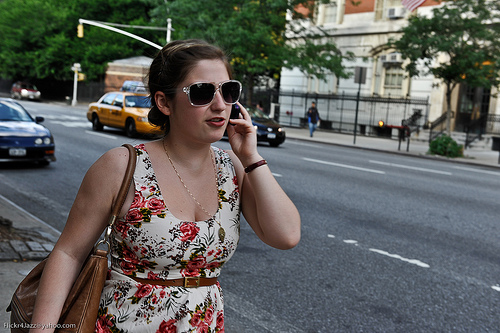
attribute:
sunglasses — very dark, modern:
[165, 78, 243, 107]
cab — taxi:
[82, 76, 162, 139]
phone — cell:
[226, 100, 241, 128]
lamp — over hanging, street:
[74, 21, 85, 40]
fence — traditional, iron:
[37, 76, 429, 141]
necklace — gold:
[158, 140, 228, 242]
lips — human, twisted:
[198, 115, 227, 127]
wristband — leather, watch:
[239, 157, 269, 173]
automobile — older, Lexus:
[0, 95, 60, 175]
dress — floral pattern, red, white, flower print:
[91, 141, 244, 331]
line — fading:
[340, 234, 430, 277]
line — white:
[338, 224, 436, 291]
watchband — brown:
[239, 158, 270, 173]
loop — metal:
[93, 235, 114, 256]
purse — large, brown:
[5, 139, 142, 328]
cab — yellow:
[84, 87, 162, 140]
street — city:
[12, 98, 499, 327]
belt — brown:
[135, 273, 224, 293]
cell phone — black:
[231, 101, 241, 121]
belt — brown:
[172, 264, 209, 298]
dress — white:
[123, 168, 255, 328]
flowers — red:
[180, 250, 206, 269]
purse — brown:
[43, 259, 119, 322]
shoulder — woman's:
[86, 138, 142, 210]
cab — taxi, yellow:
[81, 93, 149, 131]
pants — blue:
[302, 115, 318, 132]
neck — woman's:
[168, 135, 207, 159]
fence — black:
[311, 81, 378, 136]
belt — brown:
[115, 270, 221, 292]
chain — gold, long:
[167, 167, 211, 217]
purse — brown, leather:
[67, 251, 119, 326]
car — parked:
[0, 107, 75, 178]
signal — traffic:
[71, 18, 91, 51]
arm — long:
[82, 19, 150, 49]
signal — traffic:
[70, 25, 94, 45]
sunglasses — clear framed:
[174, 80, 240, 102]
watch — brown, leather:
[236, 149, 270, 179]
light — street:
[71, 21, 87, 43]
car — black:
[0, 87, 77, 164]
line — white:
[360, 225, 433, 273]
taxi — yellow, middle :
[84, 90, 151, 130]